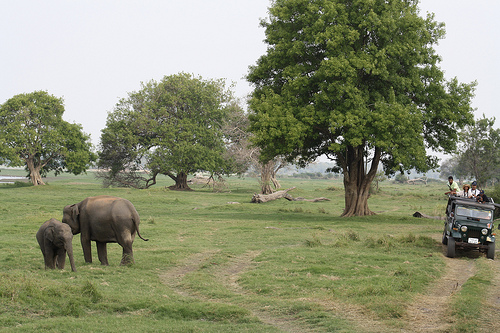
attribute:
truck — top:
[443, 197, 493, 259]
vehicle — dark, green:
[441, 192, 496, 262]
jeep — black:
[438, 183, 498, 266]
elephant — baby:
[34, 217, 81, 272]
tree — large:
[242, 0, 478, 216]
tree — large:
[95, 69, 254, 187]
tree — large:
[1, 88, 99, 186]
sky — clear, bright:
[1, 0, 499, 167]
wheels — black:
[435, 228, 497, 263]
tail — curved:
[129, 217, 150, 243]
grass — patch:
[21, 262, 228, 326]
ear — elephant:
[65, 200, 78, 218]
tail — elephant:
[130, 207, 144, 243]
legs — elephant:
[76, 249, 109, 270]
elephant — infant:
[19, 216, 85, 276]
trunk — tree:
[249, 175, 299, 212]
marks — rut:
[185, 239, 261, 322]